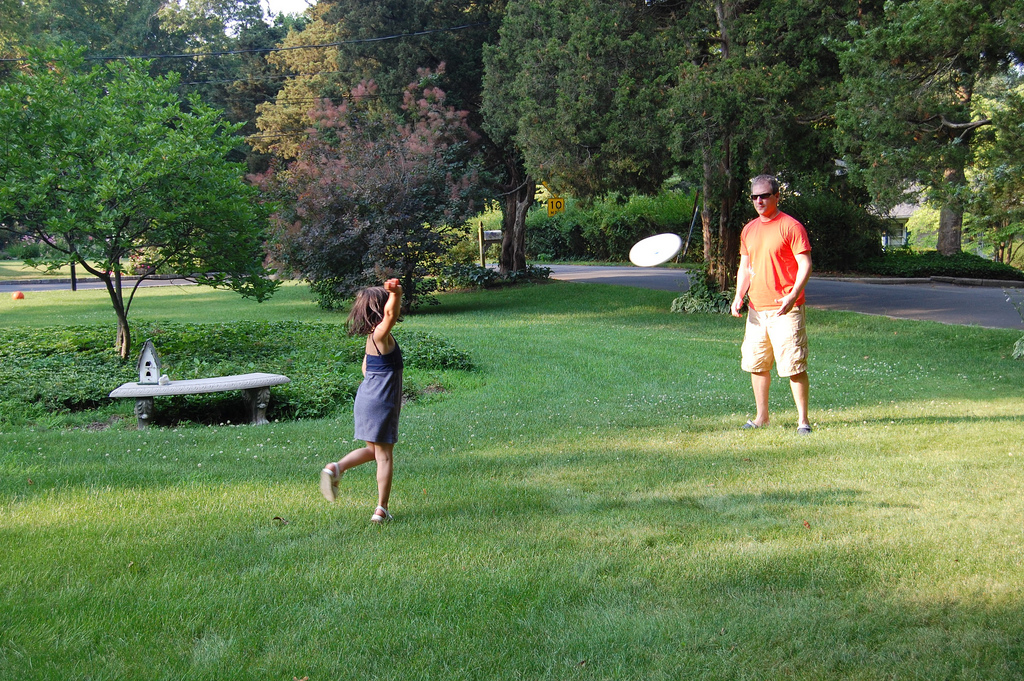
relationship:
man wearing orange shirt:
[724, 169, 819, 435] [740, 203, 810, 306]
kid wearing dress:
[320, 276, 435, 521] [355, 330, 407, 448]